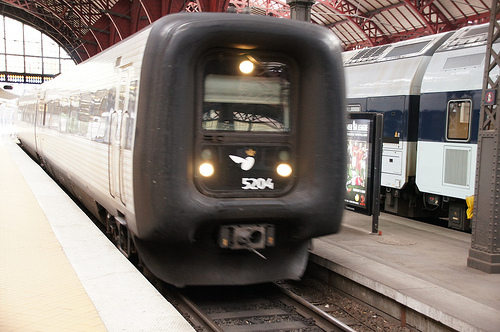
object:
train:
[2, 14, 347, 287]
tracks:
[164, 283, 354, 330]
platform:
[3, 135, 195, 332]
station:
[1, 2, 499, 331]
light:
[199, 161, 215, 176]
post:
[373, 113, 382, 234]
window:
[202, 76, 289, 131]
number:
[240, 179, 253, 191]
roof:
[2, 0, 500, 68]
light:
[276, 164, 293, 178]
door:
[107, 66, 138, 205]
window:
[7, 53, 27, 74]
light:
[239, 59, 253, 75]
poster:
[347, 119, 372, 209]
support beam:
[465, 0, 500, 274]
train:
[346, 20, 499, 241]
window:
[445, 100, 471, 142]